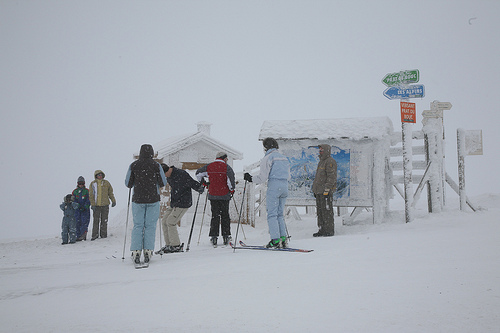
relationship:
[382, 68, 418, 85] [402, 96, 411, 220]
sign on pole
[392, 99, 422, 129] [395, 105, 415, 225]
red sign on pole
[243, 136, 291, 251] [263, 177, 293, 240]
person with pants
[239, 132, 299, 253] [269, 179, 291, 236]
woman with blue pants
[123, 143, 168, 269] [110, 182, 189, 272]
person has pants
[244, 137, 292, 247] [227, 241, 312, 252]
man on ski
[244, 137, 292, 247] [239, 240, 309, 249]
man on ski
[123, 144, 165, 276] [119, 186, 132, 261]
person on skis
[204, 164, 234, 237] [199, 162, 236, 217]
man wearing red jacket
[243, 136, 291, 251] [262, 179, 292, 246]
person wearing pants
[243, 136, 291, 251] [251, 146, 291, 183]
person wearing jacket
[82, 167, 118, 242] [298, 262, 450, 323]
person on snow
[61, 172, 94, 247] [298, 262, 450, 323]
person on snow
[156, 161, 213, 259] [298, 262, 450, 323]
person on snow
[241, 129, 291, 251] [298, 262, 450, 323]
person on snow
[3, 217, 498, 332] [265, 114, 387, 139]
snow on roof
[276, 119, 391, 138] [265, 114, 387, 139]
snow on roof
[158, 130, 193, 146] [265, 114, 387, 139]
snow on roof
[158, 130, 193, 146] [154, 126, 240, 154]
snow on roof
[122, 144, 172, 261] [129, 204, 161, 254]
person in blue pants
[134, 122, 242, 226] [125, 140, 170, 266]
building beyond person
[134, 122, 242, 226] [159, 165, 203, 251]
building beyond person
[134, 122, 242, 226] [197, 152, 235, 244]
building beyond person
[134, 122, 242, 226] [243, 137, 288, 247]
building beyond person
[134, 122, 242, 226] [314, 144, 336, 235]
building beyond person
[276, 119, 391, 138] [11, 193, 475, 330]
snow on ground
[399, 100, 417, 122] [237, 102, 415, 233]
red sign on building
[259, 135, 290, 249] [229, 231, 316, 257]
woman on skis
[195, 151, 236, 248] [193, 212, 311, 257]
person on skis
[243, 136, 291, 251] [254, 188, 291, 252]
person wearing pants